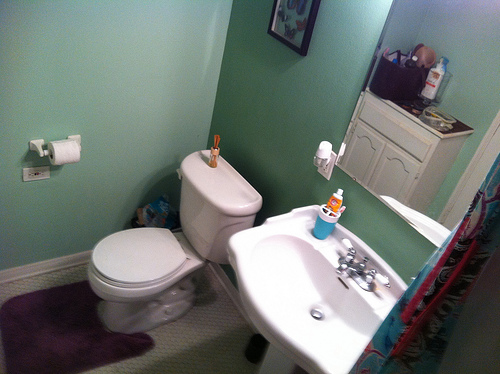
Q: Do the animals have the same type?
A: Yes, all the animals are bugs.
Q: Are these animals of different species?
A: No, all the animals are bugs.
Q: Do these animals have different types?
A: No, all the animals are bugs.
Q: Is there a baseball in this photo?
A: No, there are no baseballs.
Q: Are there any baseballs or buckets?
A: No, there are no baseballs or buckets.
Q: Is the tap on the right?
A: Yes, the tap is on the right of the image.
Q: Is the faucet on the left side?
A: No, the faucet is on the right of the image.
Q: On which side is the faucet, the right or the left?
A: The faucet is on the right of the image.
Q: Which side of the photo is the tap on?
A: The tap is on the right of the image.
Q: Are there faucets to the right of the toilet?
A: Yes, there is a faucet to the right of the toilet.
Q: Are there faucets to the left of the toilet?
A: No, the faucet is to the right of the toilet.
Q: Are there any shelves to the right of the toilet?
A: No, there is a faucet to the right of the toilet.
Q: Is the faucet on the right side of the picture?
A: Yes, the faucet is on the right of the image.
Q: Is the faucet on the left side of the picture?
A: No, the faucet is on the right of the image.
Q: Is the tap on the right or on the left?
A: The tap is on the right of the image.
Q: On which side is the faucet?
A: The faucet is on the right of the image.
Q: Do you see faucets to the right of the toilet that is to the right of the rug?
A: Yes, there is a faucet to the right of the toilet.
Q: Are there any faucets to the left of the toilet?
A: No, the faucet is to the right of the toilet.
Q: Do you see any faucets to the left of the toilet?
A: No, the faucet is to the right of the toilet.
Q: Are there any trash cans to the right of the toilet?
A: No, there is a faucet to the right of the toilet.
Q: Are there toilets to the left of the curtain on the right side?
A: Yes, there is a toilet to the left of the curtain.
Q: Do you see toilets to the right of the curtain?
A: No, the toilet is to the left of the curtain.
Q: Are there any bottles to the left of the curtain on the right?
A: No, there is a toilet to the left of the curtain.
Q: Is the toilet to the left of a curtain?
A: Yes, the toilet is to the left of a curtain.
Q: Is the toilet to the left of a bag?
A: No, the toilet is to the left of a curtain.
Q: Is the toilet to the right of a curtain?
A: No, the toilet is to the left of a curtain.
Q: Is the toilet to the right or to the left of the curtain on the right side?
A: The toilet is to the left of the curtain.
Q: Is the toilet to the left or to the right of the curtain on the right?
A: The toilet is to the left of the curtain.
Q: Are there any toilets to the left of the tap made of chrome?
A: Yes, there is a toilet to the left of the faucet.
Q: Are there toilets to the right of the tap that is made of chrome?
A: No, the toilet is to the left of the tap.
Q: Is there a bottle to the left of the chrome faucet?
A: No, there is a toilet to the left of the faucet.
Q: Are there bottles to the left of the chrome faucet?
A: No, there is a toilet to the left of the faucet.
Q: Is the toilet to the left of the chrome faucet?
A: Yes, the toilet is to the left of the tap.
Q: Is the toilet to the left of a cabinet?
A: No, the toilet is to the left of the tap.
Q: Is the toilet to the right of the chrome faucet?
A: No, the toilet is to the left of the faucet.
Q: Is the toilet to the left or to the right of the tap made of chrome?
A: The toilet is to the left of the faucet.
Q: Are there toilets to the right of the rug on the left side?
A: Yes, there is a toilet to the right of the rug.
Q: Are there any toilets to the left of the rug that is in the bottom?
A: No, the toilet is to the right of the rug.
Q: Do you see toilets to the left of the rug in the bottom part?
A: No, the toilet is to the right of the rug.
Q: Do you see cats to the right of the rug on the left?
A: No, there is a toilet to the right of the rug.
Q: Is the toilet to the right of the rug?
A: Yes, the toilet is to the right of the rug.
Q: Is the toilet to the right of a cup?
A: No, the toilet is to the right of the rug.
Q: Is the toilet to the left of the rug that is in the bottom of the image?
A: No, the toilet is to the right of the rug.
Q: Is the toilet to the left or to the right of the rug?
A: The toilet is to the right of the rug.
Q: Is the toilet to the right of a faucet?
A: No, the toilet is to the left of a faucet.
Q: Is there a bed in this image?
A: No, there are no beds.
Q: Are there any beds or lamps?
A: No, there are no beds or lamps.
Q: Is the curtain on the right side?
A: Yes, the curtain is on the right of the image.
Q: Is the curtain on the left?
A: No, the curtain is on the right of the image.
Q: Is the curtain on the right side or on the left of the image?
A: The curtain is on the right of the image.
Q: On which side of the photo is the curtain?
A: The curtain is on the right of the image.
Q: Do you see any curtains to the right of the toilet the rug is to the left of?
A: Yes, there is a curtain to the right of the toilet.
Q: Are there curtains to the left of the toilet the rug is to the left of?
A: No, the curtain is to the right of the toilet.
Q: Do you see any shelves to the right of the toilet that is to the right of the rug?
A: No, there is a curtain to the right of the toilet.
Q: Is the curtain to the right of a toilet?
A: Yes, the curtain is to the right of a toilet.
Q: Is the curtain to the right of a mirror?
A: No, the curtain is to the right of a toilet.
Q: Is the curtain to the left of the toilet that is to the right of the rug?
A: No, the curtain is to the right of the toilet.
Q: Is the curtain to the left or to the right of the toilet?
A: The curtain is to the right of the toilet.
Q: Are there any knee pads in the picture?
A: No, there are no knee pads.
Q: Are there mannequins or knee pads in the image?
A: No, there are no knee pads or mannequins.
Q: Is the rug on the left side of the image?
A: Yes, the rug is on the left of the image.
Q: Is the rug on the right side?
A: No, the rug is on the left of the image.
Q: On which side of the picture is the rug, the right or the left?
A: The rug is on the left of the image.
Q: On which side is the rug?
A: The rug is on the left of the image.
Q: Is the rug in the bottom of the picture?
A: Yes, the rug is in the bottom of the image.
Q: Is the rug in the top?
A: No, the rug is in the bottom of the image.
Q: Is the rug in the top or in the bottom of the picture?
A: The rug is in the bottom of the image.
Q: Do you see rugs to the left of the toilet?
A: Yes, there is a rug to the left of the toilet.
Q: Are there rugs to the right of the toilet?
A: No, the rug is to the left of the toilet.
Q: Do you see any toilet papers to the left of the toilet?
A: No, there is a rug to the left of the toilet.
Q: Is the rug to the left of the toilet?
A: Yes, the rug is to the left of the toilet.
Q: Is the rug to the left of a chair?
A: No, the rug is to the left of the toilet.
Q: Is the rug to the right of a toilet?
A: No, the rug is to the left of a toilet.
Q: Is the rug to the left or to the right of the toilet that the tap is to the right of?
A: The rug is to the left of the toilet.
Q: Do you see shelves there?
A: No, there are no shelves.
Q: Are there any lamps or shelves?
A: No, there are no shelves or lamps.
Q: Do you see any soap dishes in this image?
A: No, there are no soap dishes.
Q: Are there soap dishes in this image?
A: No, there are no soap dishes.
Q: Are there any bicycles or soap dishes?
A: No, there are no soap dishes or bicycles.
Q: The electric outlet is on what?
A: The electric outlet is on the wall.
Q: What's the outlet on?
A: The electric outlet is on the wall.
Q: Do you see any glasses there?
A: No, there are no glasses.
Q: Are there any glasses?
A: No, there are no glasses.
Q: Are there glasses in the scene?
A: No, there are no glasses.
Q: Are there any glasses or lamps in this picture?
A: No, there are no glasses or lamps.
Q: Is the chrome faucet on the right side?
A: Yes, the faucet is on the right of the image.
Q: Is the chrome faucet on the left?
A: No, the tap is on the right of the image.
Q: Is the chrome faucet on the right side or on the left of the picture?
A: The faucet is on the right of the image.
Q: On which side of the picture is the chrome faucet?
A: The tap is on the right of the image.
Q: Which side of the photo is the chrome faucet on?
A: The tap is on the right of the image.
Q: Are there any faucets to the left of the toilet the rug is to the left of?
A: No, the faucet is to the right of the toilet.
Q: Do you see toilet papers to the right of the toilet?
A: No, there is a faucet to the right of the toilet.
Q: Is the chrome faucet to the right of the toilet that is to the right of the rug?
A: Yes, the tap is to the right of the toilet.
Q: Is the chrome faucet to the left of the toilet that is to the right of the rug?
A: No, the tap is to the right of the toilet.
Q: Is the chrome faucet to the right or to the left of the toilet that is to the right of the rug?
A: The tap is to the right of the toilet.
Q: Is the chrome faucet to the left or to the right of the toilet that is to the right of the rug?
A: The tap is to the right of the toilet.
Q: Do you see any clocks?
A: No, there are no clocks.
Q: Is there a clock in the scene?
A: No, there are no clocks.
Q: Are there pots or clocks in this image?
A: No, there are no clocks or pots.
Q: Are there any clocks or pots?
A: No, there are no clocks or pots.